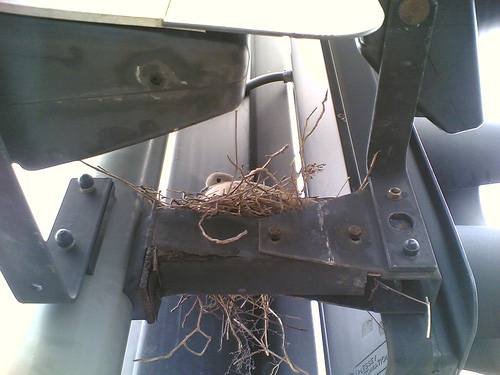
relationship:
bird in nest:
[172, 151, 270, 188] [184, 199, 303, 260]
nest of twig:
[184, 199, 303, 260] [268, 87, 333, 207]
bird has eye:
[172, 151, 270, 188] [207, 174, 230, 188]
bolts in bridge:
[42, 154, 113, 307] [312, 37, 493, 338]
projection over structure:
[2, 1, 385, 57] [4, 209, 498, 324]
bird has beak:
[172, 151, 270, 188] [189, 185, 212, 198]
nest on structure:
[184, 199, 303, 260] [4, 209, 498, 324]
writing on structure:
[335, 346, 395, 373] [4, 209, 498, 324]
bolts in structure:
[42, 154, 113, 307] [4, 209, 498, 324]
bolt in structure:
[390, 224, 438, 262] [4, 209, 498, 324]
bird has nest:
[172, 151, 270, 188] [169, 300, 295, 363]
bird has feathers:
[172, 151, 270, 188] [236, 181, 280, 196]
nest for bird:
[184, 199, 303, 260] [172, 151, 270, 188]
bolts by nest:
[42, 154, 113, 307] [184, 199, 303, 260]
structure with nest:
[4, 209, 498, 324] [184, 199, 303, 260]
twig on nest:
[268, 87, 333, 207] [184, 199, 303, 260]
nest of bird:
[184, 199, 303, 260] [172, 151, 270, 188]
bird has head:
[172, 151, 270, 188] [199, 165, 235, 192]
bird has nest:
[172, 151, 270, 188] [184, 199, 303, 260]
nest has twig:
[184, 199, 303, 260] [268, 87, 333, 207]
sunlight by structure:
[6, 142, 102, 216] [4, 209, 498, 324]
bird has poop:
[172, 151, 270, 188] [303, 187, 343, 274]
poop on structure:
[303, 187, 343, 274] [4, 209, 498, 324]